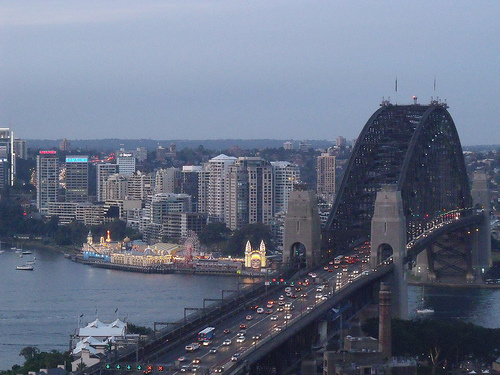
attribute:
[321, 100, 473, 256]
arch — black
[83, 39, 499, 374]
bridge — huge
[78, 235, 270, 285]
waterfront — huge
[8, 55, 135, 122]
sky — blue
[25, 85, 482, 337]
city' — huge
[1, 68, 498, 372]
city — big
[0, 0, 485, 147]
sky — blue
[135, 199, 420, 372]
bridge — suspension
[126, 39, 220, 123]
sky — blue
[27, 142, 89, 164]
signs — lighted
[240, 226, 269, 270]
building — ornate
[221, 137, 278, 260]
skyscraper — huge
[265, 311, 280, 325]
vehicle — small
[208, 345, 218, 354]
car — small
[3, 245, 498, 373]
river — calm, blue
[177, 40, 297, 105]
sky — hazy, blue, overcast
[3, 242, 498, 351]
river — huge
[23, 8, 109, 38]
clouds — white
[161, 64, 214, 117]
sky — blue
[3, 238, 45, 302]
boats/river — huge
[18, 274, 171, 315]
water — dark blue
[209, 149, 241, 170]
roof — blue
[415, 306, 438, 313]
boat — huge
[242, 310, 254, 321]
vehicle — small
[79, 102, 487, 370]
bridge — huge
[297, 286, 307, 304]
vehicle — small